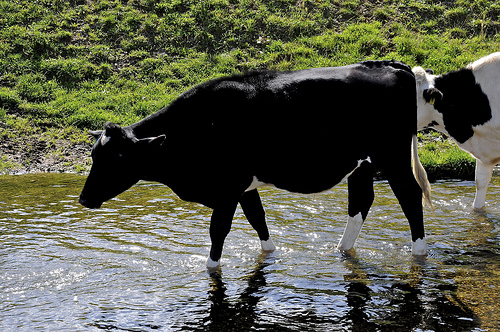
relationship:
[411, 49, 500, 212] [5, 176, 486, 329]
bovine walking in water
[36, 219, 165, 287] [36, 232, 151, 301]
ripple on water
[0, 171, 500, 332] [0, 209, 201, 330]
ripple in water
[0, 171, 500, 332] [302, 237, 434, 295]
ripple in water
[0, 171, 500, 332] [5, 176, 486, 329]
ripple in water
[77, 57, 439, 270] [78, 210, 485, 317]
animal in water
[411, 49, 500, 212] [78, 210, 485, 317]
bovine in water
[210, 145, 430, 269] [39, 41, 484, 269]
markings on cow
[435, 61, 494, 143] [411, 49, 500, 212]
black marking on bovine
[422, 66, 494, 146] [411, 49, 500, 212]
black marking on bovine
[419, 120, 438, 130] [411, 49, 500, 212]
black marking on bovine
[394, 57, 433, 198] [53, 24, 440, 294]
tail on cow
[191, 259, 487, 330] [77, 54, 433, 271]
reflection of animal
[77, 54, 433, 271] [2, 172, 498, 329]
animal in stream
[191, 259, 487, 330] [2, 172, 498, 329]
reflection in stream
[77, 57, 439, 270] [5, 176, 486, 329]
animal in water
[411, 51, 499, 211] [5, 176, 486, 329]
bovine in water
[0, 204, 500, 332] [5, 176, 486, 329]
reflection in water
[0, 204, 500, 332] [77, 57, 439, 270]
reflection of animal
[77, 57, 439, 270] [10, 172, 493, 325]
animal in brook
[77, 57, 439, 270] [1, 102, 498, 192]
animal near riverbank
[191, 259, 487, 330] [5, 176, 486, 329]
reflection in water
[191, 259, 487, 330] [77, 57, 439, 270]
reflection of animal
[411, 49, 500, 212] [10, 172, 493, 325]
bovine in brook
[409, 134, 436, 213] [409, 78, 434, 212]
white hair on tail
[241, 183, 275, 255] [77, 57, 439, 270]
leg of animal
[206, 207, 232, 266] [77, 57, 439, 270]
leg of animal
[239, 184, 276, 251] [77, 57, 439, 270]
leg of animal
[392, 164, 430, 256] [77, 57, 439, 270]
leg of animal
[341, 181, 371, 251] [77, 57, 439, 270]
leg of animal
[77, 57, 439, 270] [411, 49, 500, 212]
animal walking with bovine